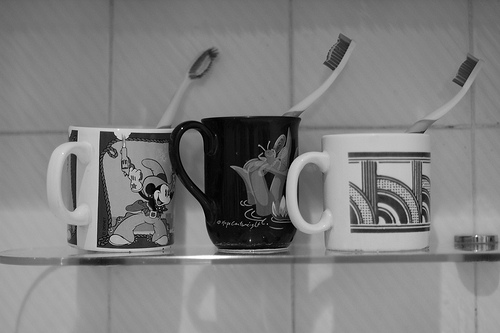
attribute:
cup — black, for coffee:
[170, 111, 301, 253]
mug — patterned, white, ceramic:
[286, 134, 435, 254]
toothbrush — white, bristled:
[408, 51, 482, 135]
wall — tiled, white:
[2, 0, 500, 332]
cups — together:
[42, 111, 438, 258]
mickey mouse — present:
[109, 154, 173, 247]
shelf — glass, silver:
[1, 245, 500, 264]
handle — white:
[284, 153, 332, 234]